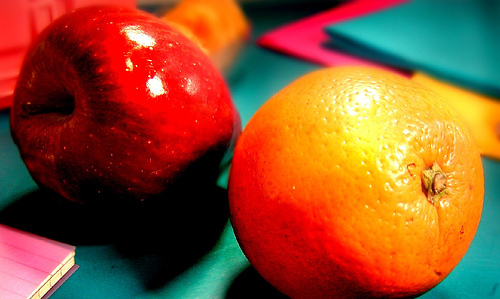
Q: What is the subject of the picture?
A: Fruit.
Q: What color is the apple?
A: Red.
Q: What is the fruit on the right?
A: Orange.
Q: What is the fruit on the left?
A: Apple.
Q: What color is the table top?
A: Blue.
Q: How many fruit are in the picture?
A: Two.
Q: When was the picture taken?
A: Daytime.